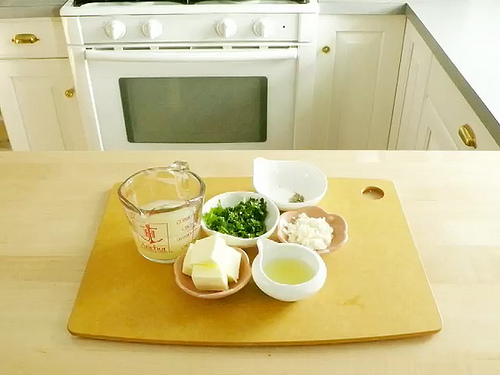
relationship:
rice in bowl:
[297, 218, 328, 242] [276, 201, 349, 248]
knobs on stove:
[101, 19, 274, 39] [50, 0, 318, 143]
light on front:
[280, 19, 292, 31] [63, 10, 330, 156]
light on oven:
[280, 19, 292, 31] [67, 36, 322, 148]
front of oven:
[63, 10, 330, 156] [67, 36, 322, 148]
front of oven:
[103, 63, 281, 142] [67, 36, 322, 148]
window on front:
[120, 75, 278, 145] [103, 63, 281, 142]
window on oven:
[120, 75, 278, 145] [67, 36, 322, 148]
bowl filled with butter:
[174, 235, 248, 294] [186, 235, 241, 284]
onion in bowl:
[297, 214, 329, 243] [271, 196, 347, 251]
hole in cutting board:
[365, 181, 383, 203] [69, 179, 436, 342]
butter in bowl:
[182, 235, 241, 281] [271, 207, 347, 251]